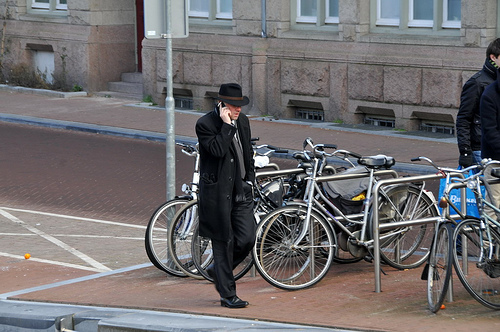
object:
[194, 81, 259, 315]
man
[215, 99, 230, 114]
phone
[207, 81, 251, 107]
hat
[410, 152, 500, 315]
bicycles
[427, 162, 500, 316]
bicycles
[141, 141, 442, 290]
bicycles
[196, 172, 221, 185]
gloves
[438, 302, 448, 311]
orange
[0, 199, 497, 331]
floor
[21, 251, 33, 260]
orange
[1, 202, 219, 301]
road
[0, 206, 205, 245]
stripes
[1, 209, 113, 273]
stripes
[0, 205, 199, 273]
stripes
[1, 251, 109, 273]
stripes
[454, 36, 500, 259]
man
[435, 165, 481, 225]
bag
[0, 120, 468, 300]
curb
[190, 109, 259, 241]
coat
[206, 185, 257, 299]
pants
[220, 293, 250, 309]
shoe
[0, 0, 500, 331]
picture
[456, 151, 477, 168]
gloves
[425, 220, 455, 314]
wheel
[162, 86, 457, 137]
basement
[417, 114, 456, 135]
windows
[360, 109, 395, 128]
windows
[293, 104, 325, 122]
windows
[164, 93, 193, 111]
windows